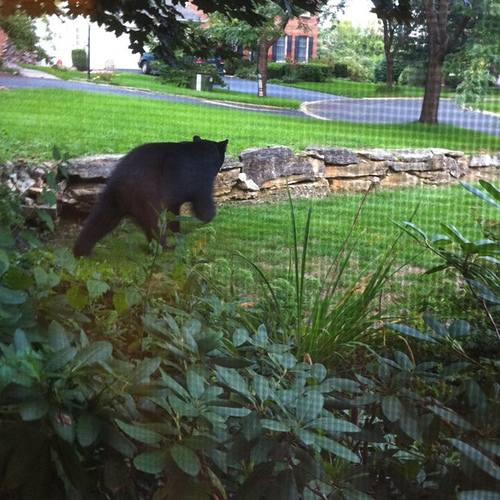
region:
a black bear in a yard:
[86, 126, 241, 251]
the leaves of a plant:
[100, 362, 212, 434]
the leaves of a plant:
[289, 234, 361, 327]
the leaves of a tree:
[179, 51, 215, 75]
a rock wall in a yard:
[275, 144, 372, 197]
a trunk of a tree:
[411, 67, 449, 125]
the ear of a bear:
[217, 135, 232, 155]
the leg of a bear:
[192, 189, 226, 227]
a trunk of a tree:
[251, 47, 276, 97]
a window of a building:
[291, 32, 319, 64]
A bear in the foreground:
[49, 94, 258, 279]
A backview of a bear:
[59, 118, 239, 267]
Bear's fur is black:
[59, 104, 241, 264]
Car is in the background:
[135, 39, 230, 87]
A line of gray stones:
[5, 138, 445, 203]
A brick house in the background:
[185, 0, 322, 66]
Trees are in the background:
[250, 0, 486, 115]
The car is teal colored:
[130, 31, 230, 91]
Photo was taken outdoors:
[15, 6, 494, 490]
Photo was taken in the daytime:
[4, 9, 488, 499]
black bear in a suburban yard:
[66, 77, 412, 315]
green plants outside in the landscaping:
[35, 266, 370, 467]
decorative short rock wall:
[241, 133, 471, 198]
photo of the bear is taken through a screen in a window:
[230, 45, 437, 195]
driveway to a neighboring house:
[12, 40, 320, 127]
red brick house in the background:
[95, 0, 335, 81]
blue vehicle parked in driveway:
[133, 33, 228, 88]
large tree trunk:
[390, 0, 453, 130]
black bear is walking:
[58, 115, 236, 257]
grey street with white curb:
[293, 70, 486, 147]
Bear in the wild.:
[48, 115, 375, 249]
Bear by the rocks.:
[58, 89, 383, 307]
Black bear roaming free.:
[72, 105, 397, 333]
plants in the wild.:
[33, 205, 316, 447]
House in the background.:
[172, 4, 490, 139]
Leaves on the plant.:
[146, 201, 258, 492]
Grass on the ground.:
[85, 170, 353, 313]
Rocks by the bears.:
[196, 137, 438, 237]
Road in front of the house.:
[162, 36, 439, 141]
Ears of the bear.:
[127, 103, 307, 173]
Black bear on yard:
[67, 130, 233, 258]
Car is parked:
[133, 42, 228, 78]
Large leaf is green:
[291, 387, 323, 425]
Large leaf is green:
[184, 364, 205, 401]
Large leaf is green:
[120, 356, 167, 386]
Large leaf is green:
[77, 335, 116, 365]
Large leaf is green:
[313, 432, 361, 463]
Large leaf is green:
[304, 415, 364, 433]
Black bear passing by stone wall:
[67, 132, 232, 257]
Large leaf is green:
[166, 438, 202, 475]